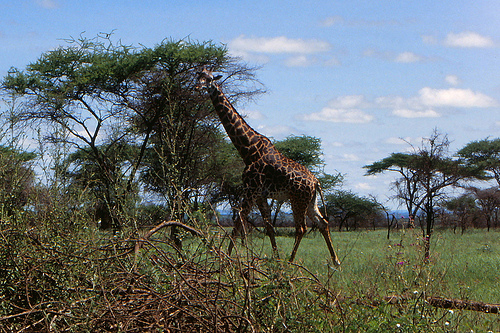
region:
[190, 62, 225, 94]
the head of a giraffe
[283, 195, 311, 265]
the leg of a giraffe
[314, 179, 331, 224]
the tail of a giraffe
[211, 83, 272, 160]
the neck of a giraffe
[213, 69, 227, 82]
the ear of a giraffe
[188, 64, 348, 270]
a giraffe on the grass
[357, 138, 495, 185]
a leafy green tree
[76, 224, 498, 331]
a green field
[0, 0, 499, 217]
a cloudy blue sky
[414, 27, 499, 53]
a white cloud in the sky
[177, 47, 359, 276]
giraffe in a field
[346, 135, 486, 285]
tree with green leaves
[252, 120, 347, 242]
tree with green leaves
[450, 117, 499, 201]
tree with green leaves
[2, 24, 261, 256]
tree with green leaves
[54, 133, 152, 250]
tree with green leaves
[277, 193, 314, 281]
long leg of a giraffe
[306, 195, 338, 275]
long leg of a giraffe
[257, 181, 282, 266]
long leg of a giraffe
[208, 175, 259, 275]
long leg of a giraffe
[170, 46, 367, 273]
a giraffe in the wild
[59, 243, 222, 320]
trees with no leaves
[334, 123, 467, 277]
a tree on the grass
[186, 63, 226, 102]
the head of the giraffe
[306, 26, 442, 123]
clouds out in the sky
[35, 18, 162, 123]
tree near the giraffe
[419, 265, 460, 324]
a piece of wood on the ground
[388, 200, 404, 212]
mountains out in the horizon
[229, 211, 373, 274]
the legs of the zebra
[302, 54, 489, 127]
a couple of more clouds in the sky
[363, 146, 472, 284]
a tall flat topped green tree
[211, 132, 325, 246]
a tall flat topped green tree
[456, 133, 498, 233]
a tall flat topped green tree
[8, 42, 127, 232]
a tall flat topped green tree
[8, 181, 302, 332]
a pile of brown sticks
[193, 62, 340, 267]
a tall tan and brown giraffe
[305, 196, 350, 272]
the leg of a tan and brown giraffe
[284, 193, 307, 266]
the leg of a tan and brown giraffe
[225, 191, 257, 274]
the leg of a tan and brown giraffe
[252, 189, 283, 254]
the leg of a tan and brown giraffe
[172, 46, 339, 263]
giraffe in the wild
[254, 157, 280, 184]
brown spots on giraffe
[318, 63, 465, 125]
white clouds scattered in sky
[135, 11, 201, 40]
bright blue sky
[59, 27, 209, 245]
tall trees with green leaves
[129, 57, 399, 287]
giraffe walking through grass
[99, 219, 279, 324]
brown twigs and branches on the ground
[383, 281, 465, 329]
small white flowers in field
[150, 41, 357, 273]
one giraffe in the wild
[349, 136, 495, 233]
many trees in the distance